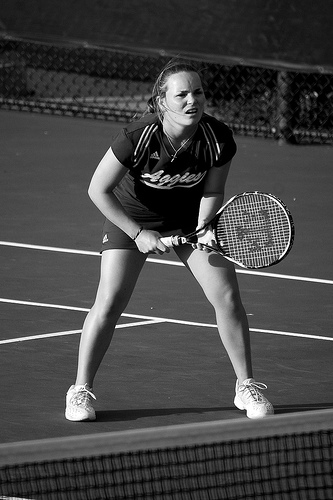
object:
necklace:
[160, 125, 200, 165]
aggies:
[137, 167, 207, 193]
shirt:
[109, 109, 237, 221]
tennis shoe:
[64, 380, 97, 424]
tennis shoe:
[230, 375, 275, 419]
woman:
[63, 60, 277, 422]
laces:
[233, 374, 267, 403]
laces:
[64, 381, 96, 406]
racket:
[158, 188, 295, 270]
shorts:
[100, 201, 231, 257]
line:
[0, 319, 161, 345]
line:
[0, 297, 332, 343]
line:
[0, 240, 332, 286]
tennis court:
[0, 114, 333, 446]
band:
[129, 225, 143, 243]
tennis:
[66, 52, 297, 426]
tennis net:
[0, 403, 333, 499]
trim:
[1, 407, 333, 473]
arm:
[88, 125, 142, 237]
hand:
[131, 227, 170, 255]